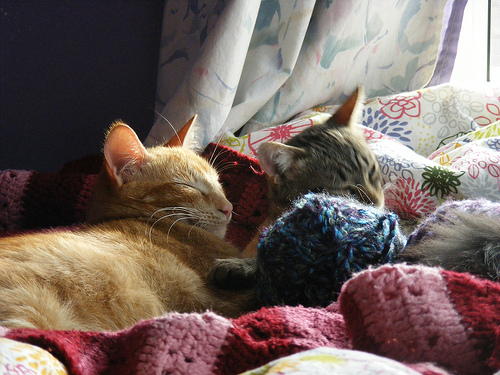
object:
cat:
[0, 112, 256, 333]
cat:
[204, 85, 391, 320]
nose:
[216, 206, 234, 222]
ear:
[101, 122, 147, 187]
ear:
[162, 113, 200, 150]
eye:
[172, 180, 206, 197]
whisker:
[184, 217, 202, 238]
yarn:
[255, 190, 409, 308]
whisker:
[144, 204, 190, 222]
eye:
[345, 186, 359, 199]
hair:
[266, 148, 293, 173]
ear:
[254, 140, 305, 179]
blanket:
[194, 80, 499, 375]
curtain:
[141, 0, 466, 152]